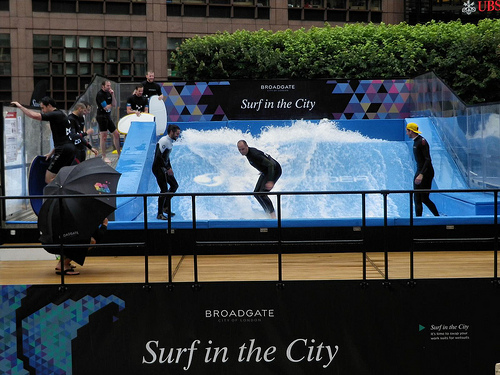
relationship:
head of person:
[237, 139, 249, 155] [231, 130, 291, 221]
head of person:
[406, 122, 422, 137] [396, 114, 446, 215]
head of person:
[104, 78, 115, 93] [94, 74, 125, 166]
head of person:
[36, 95, 58, 113] [13, 98, 73, 186]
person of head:
[125, 83, 145, 109] [143, 69, 158, 82]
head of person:
[165, 122, 182, 138] [149, 119, 183, 219]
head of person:
[233, 136, 253, 156] [234, 138, 280, 215]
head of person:
[404, 120, 421, 140] [405, 121, 441, 218]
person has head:
[126, 84, 149, 117] [130, 85, 142, 95]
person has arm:
[146, 120, 191, 225] [154, 147, 174, 177]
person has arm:
[405, 121, 441, 218] [413, 138, 432, 188]